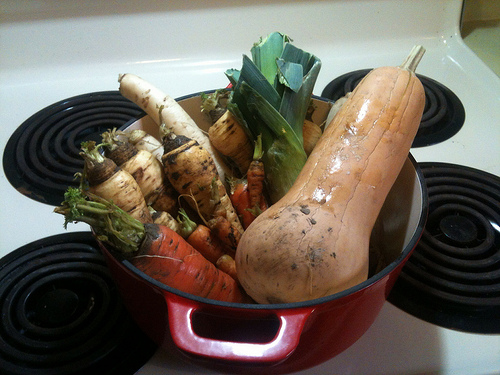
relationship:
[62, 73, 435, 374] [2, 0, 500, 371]
pot sitting on stove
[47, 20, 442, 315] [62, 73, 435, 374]
veggies are in pot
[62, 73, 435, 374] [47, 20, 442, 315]
pot has veggies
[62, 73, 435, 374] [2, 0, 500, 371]
pot on stove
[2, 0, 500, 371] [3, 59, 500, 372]
stove has 4 burners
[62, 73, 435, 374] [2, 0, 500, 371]
pot on a stove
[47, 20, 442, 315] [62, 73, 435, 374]
vegetables in a pan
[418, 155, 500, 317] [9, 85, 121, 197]
burner on stove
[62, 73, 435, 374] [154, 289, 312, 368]
pot has handle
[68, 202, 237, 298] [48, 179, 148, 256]
carrot has leaf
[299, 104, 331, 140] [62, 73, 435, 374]
artichoke in pot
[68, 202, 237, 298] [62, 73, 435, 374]
carrot in pot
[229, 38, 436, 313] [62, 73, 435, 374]
squash in pot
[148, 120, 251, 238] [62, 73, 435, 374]
turnip in pot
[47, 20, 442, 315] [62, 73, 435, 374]
vegetables in pot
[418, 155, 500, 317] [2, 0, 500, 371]
burner front of stove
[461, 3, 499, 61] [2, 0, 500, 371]
counter beside stove